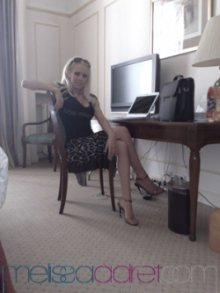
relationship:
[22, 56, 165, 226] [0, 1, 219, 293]
woman inside of room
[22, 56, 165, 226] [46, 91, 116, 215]
woman sitting in chair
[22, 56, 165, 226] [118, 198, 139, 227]
woman has shoe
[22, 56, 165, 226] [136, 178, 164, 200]
woman has shoe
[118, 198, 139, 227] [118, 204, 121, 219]
shoe has high heel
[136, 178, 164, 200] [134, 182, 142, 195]
shoe has high heel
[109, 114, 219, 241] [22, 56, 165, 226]
table beside woman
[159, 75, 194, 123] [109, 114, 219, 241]
bag on top of table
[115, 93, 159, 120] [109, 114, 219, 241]
laptop on top of table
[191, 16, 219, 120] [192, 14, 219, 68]
lamp with shade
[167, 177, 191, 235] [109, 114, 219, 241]
trash can under table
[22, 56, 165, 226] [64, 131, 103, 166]
woman wears skirt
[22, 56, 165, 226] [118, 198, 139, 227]
woman wears shoe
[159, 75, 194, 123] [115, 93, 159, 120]
bag next to laptop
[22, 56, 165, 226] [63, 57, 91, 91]
woman has head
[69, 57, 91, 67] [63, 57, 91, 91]
sunglasses on top of head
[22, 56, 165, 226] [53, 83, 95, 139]
woman wears tank top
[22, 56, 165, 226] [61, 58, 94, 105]
woman has hair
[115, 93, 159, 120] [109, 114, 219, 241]
laptop sitting on table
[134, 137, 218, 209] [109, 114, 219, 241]
wires under table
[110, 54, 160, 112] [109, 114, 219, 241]
tv sitting on table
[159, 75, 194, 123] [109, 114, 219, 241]
bag sitting on table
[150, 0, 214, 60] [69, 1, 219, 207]
picture hanging on wall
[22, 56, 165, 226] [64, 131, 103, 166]
woman wearing skirt